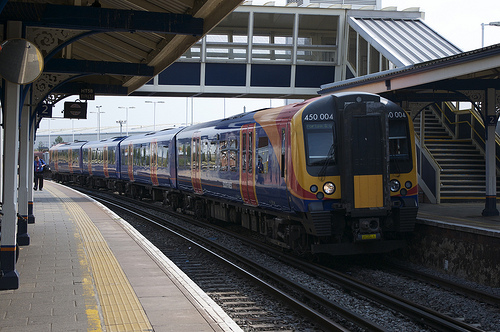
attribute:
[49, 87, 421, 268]
train — long, yellow, red, blue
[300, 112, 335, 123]
number 450 004 — white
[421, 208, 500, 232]
line — yellow, long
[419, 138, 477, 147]
stair — yellow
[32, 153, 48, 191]
man — walking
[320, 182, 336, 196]
light — white, round, on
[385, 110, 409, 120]
number print — white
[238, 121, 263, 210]
door — red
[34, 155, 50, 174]
shirt — blue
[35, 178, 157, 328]
stripe — yellow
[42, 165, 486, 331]
train track — metal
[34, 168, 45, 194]
pants — black